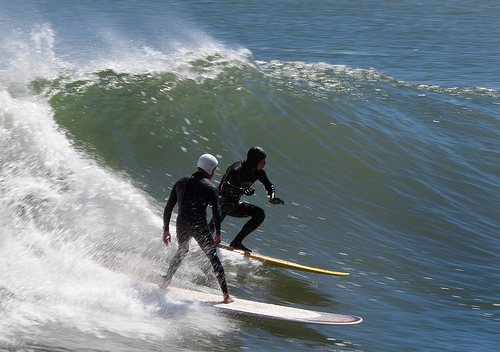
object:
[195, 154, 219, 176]
cap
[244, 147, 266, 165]
cap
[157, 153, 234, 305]
man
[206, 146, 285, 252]
man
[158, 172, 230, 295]
wetsuit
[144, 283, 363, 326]
surfboard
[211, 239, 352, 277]
surfboard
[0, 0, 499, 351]
wave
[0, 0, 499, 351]
water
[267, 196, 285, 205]
hand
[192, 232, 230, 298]
leg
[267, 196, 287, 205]
glove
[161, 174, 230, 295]
black